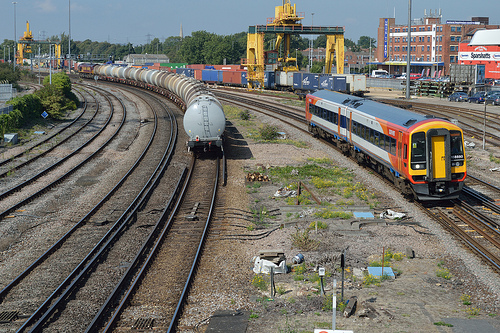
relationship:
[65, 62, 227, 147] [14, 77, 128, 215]
tanker cars are on tracks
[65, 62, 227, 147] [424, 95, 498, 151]
tanker cars are on tracks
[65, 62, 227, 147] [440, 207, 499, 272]
tanker cars are on tracks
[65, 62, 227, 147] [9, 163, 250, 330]
tanker cars are on tracks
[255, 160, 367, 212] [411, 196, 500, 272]
grass patch between tracks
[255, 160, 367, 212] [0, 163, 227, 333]
grass patch between tracks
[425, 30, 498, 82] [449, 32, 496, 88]
words are on sign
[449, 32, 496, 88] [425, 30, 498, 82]
sign has words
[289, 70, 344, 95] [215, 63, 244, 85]
freight car separate from freight car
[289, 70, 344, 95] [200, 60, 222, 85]
freight car separate from freight car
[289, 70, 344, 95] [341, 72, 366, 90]
freight car separate from freight car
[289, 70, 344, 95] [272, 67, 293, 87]
freight car separate from freight car